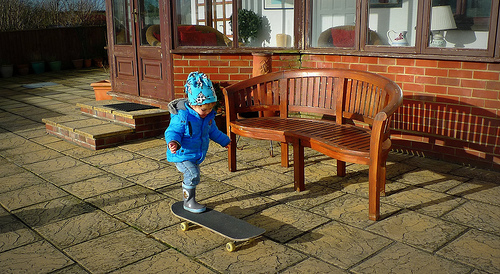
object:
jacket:
[163, 97, 233, 164]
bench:
[222, 68, 404, 222]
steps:
[42, 97, 171, 151]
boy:
[164, 71, 233, 214]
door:
[103, 0, 173, 102]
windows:
[302, 5, 360, 51]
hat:
[183, 71, 217, 106]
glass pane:
[424, 0, 491, 49]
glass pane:
[363, 0, 416, 46]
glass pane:
[309, 0, 356, 48]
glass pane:
[138, 0, 165, 47]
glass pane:
[113, 0, 134, 45]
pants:
[175, 158, 201, 213]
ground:
[1, 67, 497, 272]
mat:
[102, 102, 159, 112]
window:
[423, 0, 498, 50]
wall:
[170, 53, 498, 171]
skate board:
[170, 201, 266, 253]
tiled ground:
[0, 69, 499, 273]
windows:
[174, 0, 239, 48]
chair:
[318, 25, 384, 47]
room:
[142, 0, 499, 58]